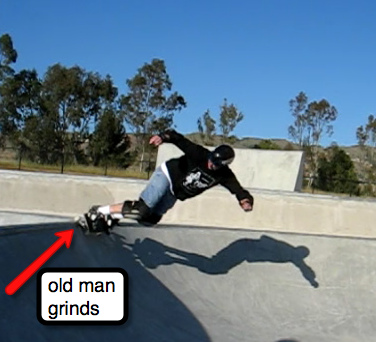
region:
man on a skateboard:
[91, 130, 250, 236]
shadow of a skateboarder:
[122, 222, 316, 290]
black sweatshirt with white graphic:
[162, 125, 241, 211]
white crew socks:
[97, 202, 106, 216]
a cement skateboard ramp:
[3, 216, 367, 338]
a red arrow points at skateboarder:
[5, 223, 78, 293]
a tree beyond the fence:
[122, 52, 185, 161]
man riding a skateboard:
[73, 94, 258, 250]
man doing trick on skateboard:
[59, 73, 267, 244]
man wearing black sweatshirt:
[67, 101, 253, 252]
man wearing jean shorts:
[59, 98, 264, 256]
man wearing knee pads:
[70, 97, 283, 255]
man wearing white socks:
[55, 93, 265, 255]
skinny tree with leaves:
[118, 37, 187, 165]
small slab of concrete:
[148, 130, 308, 202]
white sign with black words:
[24, 261, 133, 324]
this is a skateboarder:
[46, 115, 329, 333]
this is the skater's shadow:
[123, 227, 323, 281]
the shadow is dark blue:
[163, 218, 276, 279]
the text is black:
[21, 272, 115, 316]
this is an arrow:
[27, 218, 119, 289]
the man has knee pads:
[120, 153, 198, 228]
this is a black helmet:
[188, 96, 258, 165]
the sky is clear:
[65, 19, 253, 101]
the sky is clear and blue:
[99, 3, 239, 66]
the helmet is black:
[163, 102, 261, 205]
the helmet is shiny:
[171, 132, 258, 192]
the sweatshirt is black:
[156, 149, 262, 217]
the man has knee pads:
[76, 187, 154, 238]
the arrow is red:
[50, 215, 126, 296]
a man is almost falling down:
[105, 101, 259, 244]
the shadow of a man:
[132, 229, 330, 309]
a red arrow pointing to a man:
[1, 215, 78, 303]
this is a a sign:
[40, 270, 132, 331]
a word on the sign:
[43, 277, 79, 298]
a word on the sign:
[77, 275, 116, 298]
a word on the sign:
[45, 298, 105, 327]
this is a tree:
[270, 81, 341, 167]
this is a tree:
[115, 53, 184, 175]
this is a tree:
[32, 55, 115, 180]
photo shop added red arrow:
[2, 228, 72, 296]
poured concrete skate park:
[1, 139, 375, 340]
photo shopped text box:
[34, 265, 129, 326]